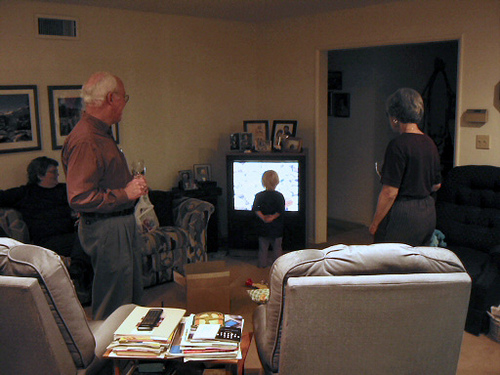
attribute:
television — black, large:
[225, 151, 307, 252]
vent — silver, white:
[35, 13, 80, 40]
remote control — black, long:
[137, 308, 163, 332]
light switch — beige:
[481, 138, 485, 145]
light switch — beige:
[476, 137, 483, 146]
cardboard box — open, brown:
[173, 256, 241, 312]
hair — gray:
[385, 85, 426, 123]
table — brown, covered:
[103, 328, 254, 374]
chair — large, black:
[433, 163, 499, 336]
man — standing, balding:
[59, 69, 149, 320]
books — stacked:
[110, 304, 244, 363]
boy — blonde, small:
[250, 168, 286, 271]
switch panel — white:
[473, 132, 491, 152]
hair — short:
[260, 169, 282, 190]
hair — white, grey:
[79, 68, 116, 107]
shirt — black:
[381, 132, 442, 197]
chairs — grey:
[1, 235, 472, 374]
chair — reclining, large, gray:
[0, 235, 140, 374]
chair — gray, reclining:
[251, 241, 474, 374]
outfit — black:
[373, 130, 441, 246]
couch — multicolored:
[0, 182, 215, 304]